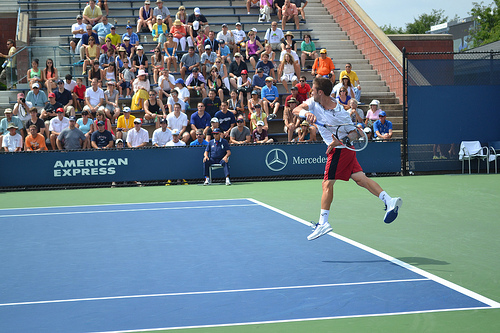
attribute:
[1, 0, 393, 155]
spectators — observant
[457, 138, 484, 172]
chair — empty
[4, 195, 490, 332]
tennis court — blue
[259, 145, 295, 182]
emblem — Mercedes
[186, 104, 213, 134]
spectator — observant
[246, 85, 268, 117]
spectator — observant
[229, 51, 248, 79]
spectator — observant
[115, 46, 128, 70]
spectator — observant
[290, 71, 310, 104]
spectator — observant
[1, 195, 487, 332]
court — blue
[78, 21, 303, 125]
spectators — observant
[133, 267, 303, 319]
line — white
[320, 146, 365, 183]
shorts — red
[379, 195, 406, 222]
tennis shoe — white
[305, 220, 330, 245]
tennis shoe — white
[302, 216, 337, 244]
shoe — white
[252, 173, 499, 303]
line — white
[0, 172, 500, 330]
court — blue, white, concrete court, blue painted, green